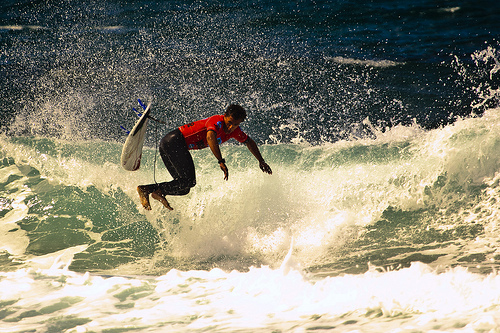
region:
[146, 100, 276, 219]
man falling off the surfboard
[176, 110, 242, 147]
red shirt surfer is wearing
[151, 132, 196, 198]
black wetsuit surfer is wearing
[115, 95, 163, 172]
white surfboard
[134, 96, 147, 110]
blue fin on bottom of white surfboard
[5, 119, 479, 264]
wave behind the surfer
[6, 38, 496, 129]
spray coming off wave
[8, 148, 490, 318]
white foam in the wave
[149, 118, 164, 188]
cord connecting surfboard to surfer's ankle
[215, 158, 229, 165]
watch on surfer's wrist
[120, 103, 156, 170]
A surfboard in the air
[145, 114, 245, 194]
The man is wearing a wetsuit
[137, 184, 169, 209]
The man is not wearing shoes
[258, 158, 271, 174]
The left hand of the man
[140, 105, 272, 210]
The man fell off the surfboard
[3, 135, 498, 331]
A wave on the water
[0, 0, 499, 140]
The water behind the wave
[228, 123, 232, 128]
The nose of the man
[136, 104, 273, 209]
The man is above the wave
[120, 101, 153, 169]
The surfboard is white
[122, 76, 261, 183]
A man playing sea sketing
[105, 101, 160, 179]
A white sketing board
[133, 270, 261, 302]
A white wave water form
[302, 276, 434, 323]
A white wave water form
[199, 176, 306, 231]
A white wave water form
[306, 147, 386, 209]
A white wave water form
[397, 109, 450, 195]
A white wave water form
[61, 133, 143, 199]
A white wave water form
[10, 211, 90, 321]
A white wave water form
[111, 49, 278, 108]
A white wave water form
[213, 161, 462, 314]
raging waters crashing down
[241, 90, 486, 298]
big waves with crests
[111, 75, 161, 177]
surf board with blue handles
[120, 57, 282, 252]
man with dark hair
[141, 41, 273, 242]
surfer wearing red and black water suit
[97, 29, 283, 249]
man falling into the water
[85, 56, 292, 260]
surfer going into the ocean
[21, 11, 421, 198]
water splashing as it crests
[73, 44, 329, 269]
surfer bracing himself for the fall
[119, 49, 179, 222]
rope holding the board to the surfer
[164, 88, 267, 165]
man wearing red shirt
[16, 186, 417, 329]
green and white waves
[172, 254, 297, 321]
bright white wave foam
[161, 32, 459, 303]
water is everywhere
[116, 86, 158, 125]
small blue fin on board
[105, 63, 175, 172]
white surfboard away from surfer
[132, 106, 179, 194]
surfboard cord attached to surfer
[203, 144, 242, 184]
surfer is wearing a watch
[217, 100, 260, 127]
surfer has short black hair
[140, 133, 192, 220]
surfer is barefoot